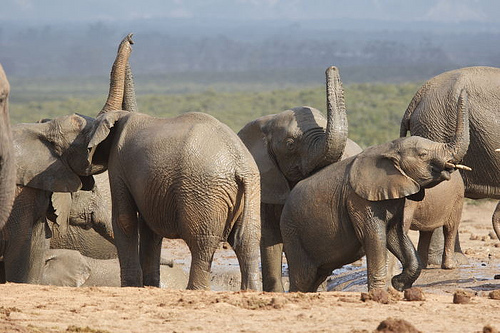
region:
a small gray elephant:
[277, 89, 473, 291]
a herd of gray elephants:
[3, 35, 498, 300]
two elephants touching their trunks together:
[10, 32, 264, 294]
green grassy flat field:
[0, 80, 421, 143]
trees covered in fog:
[1, 20, 452, 77]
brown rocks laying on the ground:
[358, 289, 498, 327]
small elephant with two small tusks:
[282, 86, 469, 291]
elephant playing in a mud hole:
[1, 35, 499, 332]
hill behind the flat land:
[11, 2, 499, 80]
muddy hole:
[156, 238, 361, 290]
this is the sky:
[153, 8, 418, 31]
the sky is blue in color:
[227, 10, 297, 25]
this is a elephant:
[296, 130, 462, 326]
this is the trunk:
[458, 80, 470, 150]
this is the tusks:
[448, 152, 480, 169]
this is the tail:
[235, 170, 260, 228]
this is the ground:
[147, 295, 284, 331]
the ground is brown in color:
[149, 279, 229, 327]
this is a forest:
[356, 85, 397, 133]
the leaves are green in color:
[208, 98, 243, 113]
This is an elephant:
[284, 88, 475, 295]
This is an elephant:
[388, 154, 478, 288]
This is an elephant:
[207, 56, 366, 305]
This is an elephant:
[64, 90, 289, 299]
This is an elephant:
[0, 31, 141, 291]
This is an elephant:
[397, 46, 498, 266]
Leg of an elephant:
[180, 223, 218, 315]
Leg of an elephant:
[233, 217, 268, 310]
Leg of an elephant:
[109, 178, 141, 313]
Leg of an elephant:
[360, 212, 395, 327]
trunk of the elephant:
[320, 65, 360, 125]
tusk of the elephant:
[435, 151, 470, 186]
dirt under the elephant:
[305, 295, 347, 325]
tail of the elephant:
[205, 156, 261, 251]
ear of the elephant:
[346, 130, 407, 195]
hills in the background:
[165, 15, 310, 90]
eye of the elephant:
[410, 145, 435, 166]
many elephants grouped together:
[0, 30, 485, 290]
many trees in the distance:
[161, 35, 263, 83]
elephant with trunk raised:
[256, 63, 368, 182]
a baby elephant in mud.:
[54, 94, 277, 285]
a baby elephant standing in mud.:
[271, 83, 485, 300]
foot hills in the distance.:
[0, 16, 497, 97]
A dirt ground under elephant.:
[0, 280, 498, 328]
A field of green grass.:
[0, 79, 495, 156]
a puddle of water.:
[136, 246, 494, 293]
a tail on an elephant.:
[230, 165, 255, 261]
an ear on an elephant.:
[344, 142, 412, 208]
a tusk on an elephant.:
[437, 160, 483, 180]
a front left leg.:
[113, 228, 161, 288]